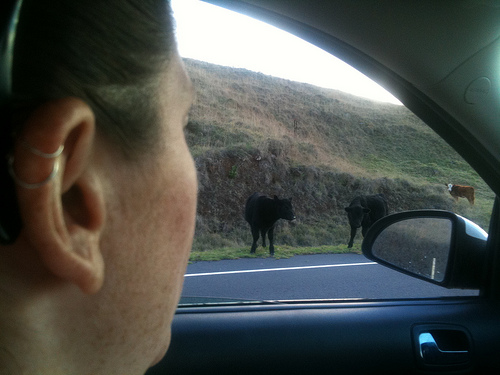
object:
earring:
[15, 132, 67, 160]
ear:
[6, 96, 107, 296]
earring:
[8, 154, 63, 192]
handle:
[416, 329, 472, 366]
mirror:
[367, 217, 465, 283]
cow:
[443, 181, 476, 209]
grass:
[227, 102, 394, 160]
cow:
[340, 189, 388, 253]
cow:
[239, 187, 296, 261]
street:
[183, 256, 475, 297]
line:
[183, 257, 379, 281]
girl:
[1, 0, 207, 374]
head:
[443, 181, 455, 195]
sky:
[167, 2, 406, 110]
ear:
[273, 194, 279, 203]